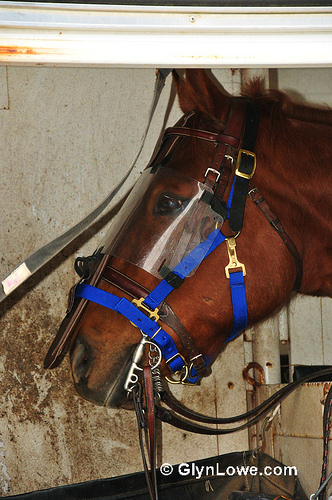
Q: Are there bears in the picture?
A: No, there are no bears.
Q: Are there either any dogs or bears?
A: No, there are no bears or dogs.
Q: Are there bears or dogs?
A: No, there are no bears or dogs.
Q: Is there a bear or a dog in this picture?
A: No, there are no bears or dogs.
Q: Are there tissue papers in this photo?
A: No, there are no tissue papers.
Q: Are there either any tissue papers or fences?
A: No, there are no tissue papers or fences.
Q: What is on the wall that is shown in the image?
A: The dirt is on the wall.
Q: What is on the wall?
A: The dirt is on the wall.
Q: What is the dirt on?
A: The dirt is on the wall.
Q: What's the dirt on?
A: The dirt is on the wall.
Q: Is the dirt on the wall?
A: Yes, the dirt is on the wall.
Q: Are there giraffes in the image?
A: No, there are no giraffes.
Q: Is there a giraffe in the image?
A: No, there are no giraffes.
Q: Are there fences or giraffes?
A: No, there are no giraffes or fences.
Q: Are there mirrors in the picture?
A: No, there are no mirrors.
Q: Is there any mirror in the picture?
A: No, there are no mirrors.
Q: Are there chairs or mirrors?
A: No, there are no mirrors or chairs.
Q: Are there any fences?
A: No, there are no fences.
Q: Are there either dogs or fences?
A: No, there are no fences or dogs.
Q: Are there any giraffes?
A: No, there are no giraffes.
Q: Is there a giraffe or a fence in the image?
A: No, there are no giraffes or fences.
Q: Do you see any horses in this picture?
A: Yes, there is a horse.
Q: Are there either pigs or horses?
A: Yes, there is a horse.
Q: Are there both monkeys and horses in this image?
A: No, there is a horse but no monkeys.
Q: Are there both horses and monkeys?
A: No, there is a horse but no monkeys.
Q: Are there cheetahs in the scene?
A: No, there are no cheetahs.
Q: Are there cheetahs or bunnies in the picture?
A: No, there are no cheetahs or bunnies.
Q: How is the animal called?
A: The animal is a horse.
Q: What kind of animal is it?
A: The animal is a horse.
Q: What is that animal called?
A: This is a horse.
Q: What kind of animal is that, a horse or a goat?
A: This is a horse.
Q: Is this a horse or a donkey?
A: This is a horse.